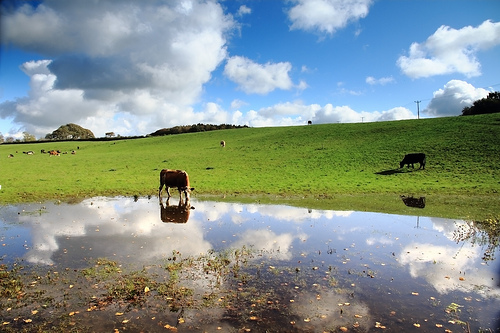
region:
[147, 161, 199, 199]
cow drinking from pond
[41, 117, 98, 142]
hill in the background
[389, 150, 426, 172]
cow grazing from field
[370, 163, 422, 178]
cow's shadow on grass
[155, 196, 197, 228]
cow's reflection on pond's surface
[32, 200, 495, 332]
clouds reflected in pond's surface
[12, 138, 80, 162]
groups of cows in the distance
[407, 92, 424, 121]
utility pole in the distance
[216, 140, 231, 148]
cow in middle of field in the distance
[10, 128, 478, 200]
grass covered hill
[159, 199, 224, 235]
reflection of a cow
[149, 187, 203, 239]
reflection of a cow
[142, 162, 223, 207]
the cow is brown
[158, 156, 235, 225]
the cow is brown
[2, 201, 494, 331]
A large puddle of water.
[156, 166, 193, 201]
A brown cow drinking water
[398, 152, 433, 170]
A black cow grazing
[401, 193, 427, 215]
A reflection of a black cow in water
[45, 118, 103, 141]
A large tree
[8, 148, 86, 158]
A group of cows in the grass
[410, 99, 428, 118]
An electricity post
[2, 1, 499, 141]
Many clouds in the sky.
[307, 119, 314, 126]
A far off cow standing on the hill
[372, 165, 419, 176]
A black cows shadow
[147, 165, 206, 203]
brown cow drink water in lake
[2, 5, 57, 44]
white clouds in blue sky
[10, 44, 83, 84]
white clouds in blue sky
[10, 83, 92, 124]
white clouds in blue sky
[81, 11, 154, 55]
white clouds in blue sky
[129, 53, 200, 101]
white clouds in blue sky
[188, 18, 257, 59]
white clouds in blue sky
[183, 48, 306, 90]
white clouds in blue sky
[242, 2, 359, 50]
white clouds in blue sky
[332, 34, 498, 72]
white clouds in blue sky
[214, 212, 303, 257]
reflection of clouds in the sky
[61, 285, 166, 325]
dirt in the leaves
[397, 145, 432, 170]
a cow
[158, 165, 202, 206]
a cow drinking water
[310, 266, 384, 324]
leaves in the water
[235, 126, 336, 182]
the short green grass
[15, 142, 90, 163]
cows in the field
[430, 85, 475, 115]
cloud in the sky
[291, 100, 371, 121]
white clouds in the sky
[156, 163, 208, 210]
a brown cow